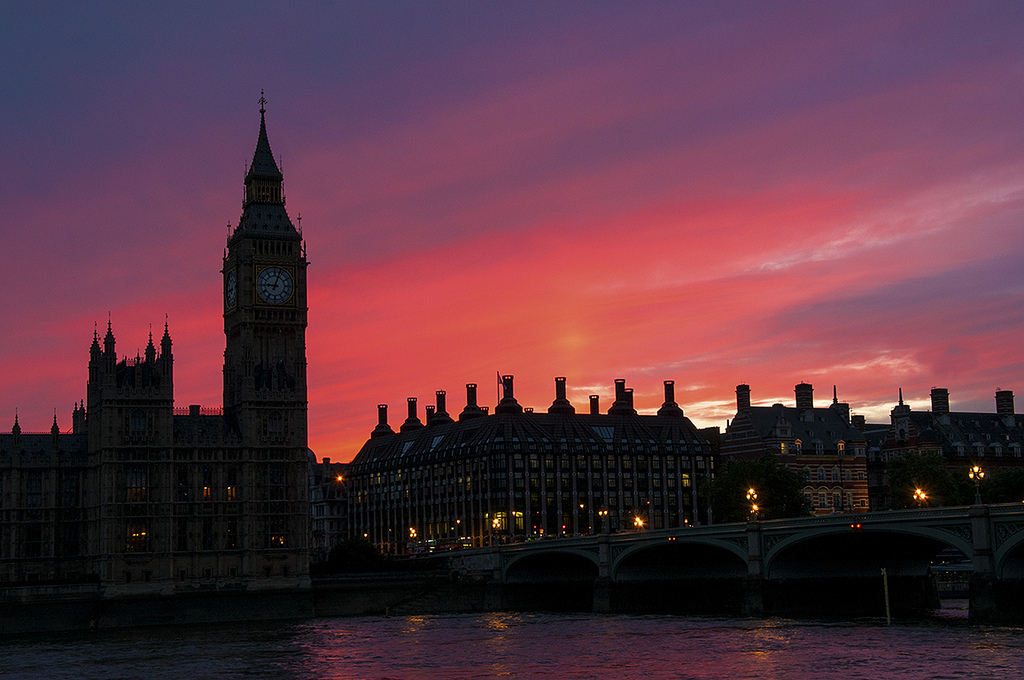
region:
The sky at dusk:
[8, 11, 1012, 413]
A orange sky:
[4, 1, 1006, 398]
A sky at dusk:
[12, 13, 1019, 383]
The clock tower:
[213, 88, 306, 463]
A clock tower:
[223, 86, 326, 425]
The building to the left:
[17, 408, 328, 609]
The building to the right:
[347, 373, 1019, 513]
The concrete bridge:
[457, 499, 1020, 595]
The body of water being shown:
[55, 608, 1021, 660]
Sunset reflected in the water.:
[275, 613, 482, 651]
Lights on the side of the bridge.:
[716, 458, 800, 569]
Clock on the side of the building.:
[228, 236, 304, 332]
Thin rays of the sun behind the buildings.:
[585, 364, 900, 434]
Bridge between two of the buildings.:
[386, 476, 1017, 628]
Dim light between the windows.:
[119, 505, 165, 572]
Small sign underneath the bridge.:
[892, 566, 994, 630]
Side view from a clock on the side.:
[213, 239, 239, 320]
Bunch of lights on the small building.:
[895, 443, 991, 492]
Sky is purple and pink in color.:
[337, 40, 977, 347]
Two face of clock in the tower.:
[205, 230, 319, 344]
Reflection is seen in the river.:
[79, 603, 962, 677]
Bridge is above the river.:
[423, 494, 1022, 643]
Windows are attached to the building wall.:
[41, 425, 718, 571]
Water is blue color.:
[269, 615, 643, 676]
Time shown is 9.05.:
[209, 248, 318, 329]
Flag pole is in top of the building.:
[473, 362, 543, 430]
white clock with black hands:
[248, 258, 307, 307]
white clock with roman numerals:
[249, 261, 310, 325]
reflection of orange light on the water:
[387, 609, 436, 642]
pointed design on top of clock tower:
[246, 84, 273, 124]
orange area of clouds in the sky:
[426, 275, 504, 356]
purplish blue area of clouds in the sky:
[87, 34, 208, 95]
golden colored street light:
[745, 496, 775, 526]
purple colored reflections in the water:
[543, 625, 680, 646]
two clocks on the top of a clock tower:
[217, 259, 313, 329]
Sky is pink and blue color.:
[369, 67, 727, 333]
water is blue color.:
[133, 622, 633, 677]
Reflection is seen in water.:
[291, 618, 839, 677]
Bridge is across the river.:
[464, 486, 1005, 641]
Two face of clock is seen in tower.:
[192, 254, 319, 344]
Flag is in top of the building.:
[460, 346, 534, 435]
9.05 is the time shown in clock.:
[224, 248, 304, 322]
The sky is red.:
[322, 120, 921, 390]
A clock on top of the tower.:
[239, 257, 322, 319]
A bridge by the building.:
[435, 496, 1023, 607]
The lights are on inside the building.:
[490, 451, 696, 535]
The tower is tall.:
[217, 94, 341, 582]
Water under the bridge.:
[379, 591, 953, 665]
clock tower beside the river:
[221, 68, 321, 597]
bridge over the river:
[367, 497, 1020, 608]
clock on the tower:
[255, 266, 290, 301]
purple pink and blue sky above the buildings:
[12, 13, 1022, 419]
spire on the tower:
[250, 87, 269, 120]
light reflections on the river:
[383, 591, 799, 669]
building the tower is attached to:
[7, 319, 232, 582]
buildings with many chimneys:
[375, 365, 1023, 531]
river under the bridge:
[12, 594, 1005, 678]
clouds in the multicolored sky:
[505, 193, 1021, 421]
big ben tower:
[227, 93, 311, 587]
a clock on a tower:
[257, 265, 295, 304]